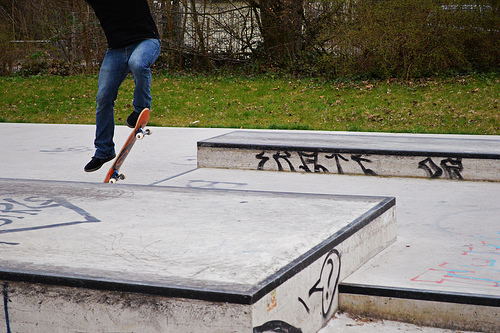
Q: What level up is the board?
A: Mid air.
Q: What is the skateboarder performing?
A: A trick.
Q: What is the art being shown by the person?
A: Skating.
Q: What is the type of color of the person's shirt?
A: Black.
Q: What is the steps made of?
A: Concrete.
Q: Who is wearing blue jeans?
A: The skateboarder.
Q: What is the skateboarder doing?
A: A trick.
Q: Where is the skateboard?
A: In the air near the person's feet.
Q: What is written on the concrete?
A: Graffiti.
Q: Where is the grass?
A: In the background under the trees.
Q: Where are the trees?
A: In the background behind the grass.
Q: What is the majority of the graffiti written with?
A: Black paint.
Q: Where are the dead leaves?
A: On the grass under the trees.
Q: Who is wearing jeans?
A: The man.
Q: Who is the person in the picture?
A: A man.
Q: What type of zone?
A: Skating.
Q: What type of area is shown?
A: Skateboard.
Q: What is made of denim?
A: Pants.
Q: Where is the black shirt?
A: On the man.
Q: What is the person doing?
A: Skateboarding.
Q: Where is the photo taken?
A: Skatepark.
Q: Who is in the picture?
A: Skateboarder.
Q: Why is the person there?
A: To skateboard.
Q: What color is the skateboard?
A: Red.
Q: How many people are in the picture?
A: One.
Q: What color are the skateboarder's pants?
A: Blue.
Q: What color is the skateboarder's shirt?
A: Black.